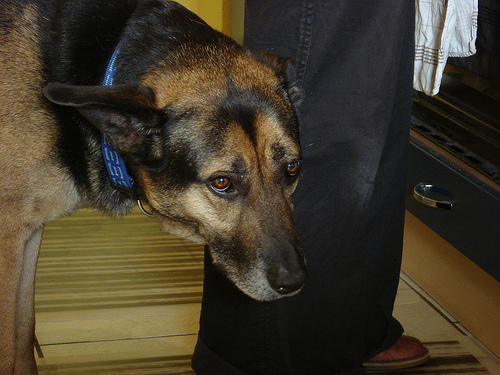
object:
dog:
[0, 0, 312, 373]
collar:
[99, 18, 156, 216]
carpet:
[33, 200, 499, 374]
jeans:
[187, 0, 417, 374]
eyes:
[205, 175, 236, 194]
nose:
[263, 272, 310, 296]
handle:
[405, 178, 454, 215]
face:
[126, 80, 307, 302]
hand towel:
[410, 0, 480, 98]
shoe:
[360, 332, 430, 370]